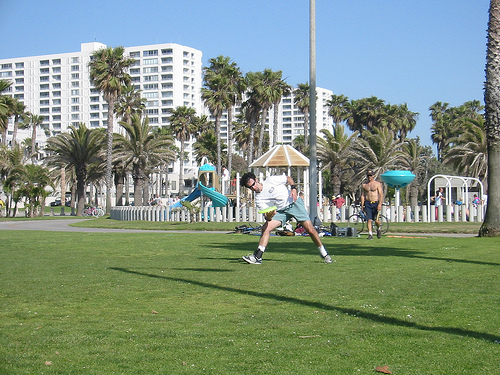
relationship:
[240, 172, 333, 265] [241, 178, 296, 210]
man wearing a shirt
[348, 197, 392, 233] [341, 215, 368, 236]
bicycle has wheel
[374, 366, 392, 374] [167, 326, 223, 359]
brown leaf on ground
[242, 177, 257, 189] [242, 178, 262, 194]
sunglasses on face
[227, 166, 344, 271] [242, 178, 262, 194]
man has face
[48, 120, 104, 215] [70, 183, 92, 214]
palm trees have trunks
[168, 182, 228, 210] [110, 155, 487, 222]
board on playground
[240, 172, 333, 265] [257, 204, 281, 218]
man catching frisbee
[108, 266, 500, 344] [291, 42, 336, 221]
shadow of street light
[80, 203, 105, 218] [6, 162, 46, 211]
bicycle leaning against tree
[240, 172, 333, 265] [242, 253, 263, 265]
man wearing shoe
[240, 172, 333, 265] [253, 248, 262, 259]
man wearing ankle brace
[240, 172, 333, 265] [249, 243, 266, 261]
man wearing ankle brace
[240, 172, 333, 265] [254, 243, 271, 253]
man wearing socks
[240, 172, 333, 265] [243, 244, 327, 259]
man wearing socks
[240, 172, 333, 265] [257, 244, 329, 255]
man wearing socks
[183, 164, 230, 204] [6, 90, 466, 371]
slides in park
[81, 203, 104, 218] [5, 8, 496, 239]
bicycle in background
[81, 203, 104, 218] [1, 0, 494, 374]
bicycle in photo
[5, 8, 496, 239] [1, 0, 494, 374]
background of photo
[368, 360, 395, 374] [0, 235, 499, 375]
brown leaf on grass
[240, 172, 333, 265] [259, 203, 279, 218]
man catching a frisbee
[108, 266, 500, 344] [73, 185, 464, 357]
shadow on grass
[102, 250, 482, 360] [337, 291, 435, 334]
shadow on ground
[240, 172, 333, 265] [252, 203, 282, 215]
man playing frisbee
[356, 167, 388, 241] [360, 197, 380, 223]
man wearing blue shorts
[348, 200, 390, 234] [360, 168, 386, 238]
bicycle behind man